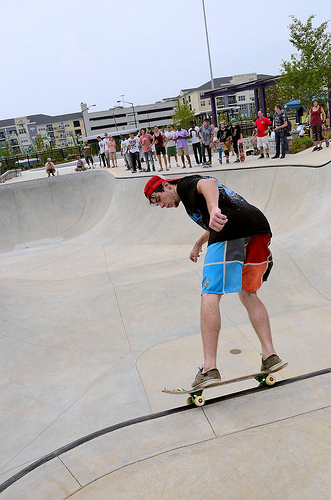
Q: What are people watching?
A: Skateboard.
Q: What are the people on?
A: Skatepark.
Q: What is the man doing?
A: Skateboarding.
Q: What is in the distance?
A: Building.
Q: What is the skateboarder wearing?
A: Black shirt.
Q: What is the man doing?
A: Skating.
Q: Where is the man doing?
A: On ramp.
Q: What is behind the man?
A: Building.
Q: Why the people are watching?
A: Enjoying.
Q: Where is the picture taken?
A: Skatepark.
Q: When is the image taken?
A: When skating.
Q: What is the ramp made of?
A: Cement.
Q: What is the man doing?
A: Skateboarding.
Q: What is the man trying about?
A: Keep balance.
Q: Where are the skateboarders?
A: A skate park.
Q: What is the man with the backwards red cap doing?
A: Skateboarding.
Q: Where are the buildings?
A: Behind the skate park.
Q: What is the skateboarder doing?
A: A skateboard trick.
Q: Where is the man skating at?
A: A skateboard park.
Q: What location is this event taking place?
A: A skateboard park.